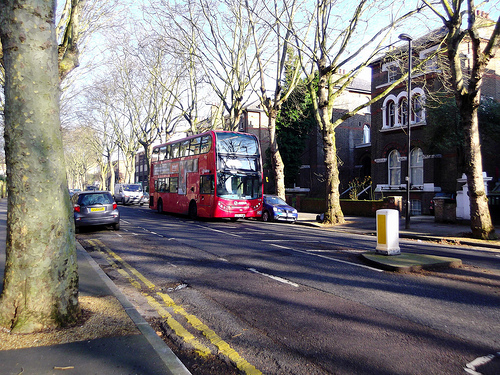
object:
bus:
[148, 131, 263, 222]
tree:
[0, 0, 88, 339]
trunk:
[3, 42, 85, 332]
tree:
[423, 0, 500, 239]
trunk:
[460, 138, 492, 239]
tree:
[279, 0, 414, 226]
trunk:
[321, 152, 346, 224]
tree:
[236, 0, 314, 201]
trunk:
[267, 145, 287, 199]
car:
[74, 191, 121, 233]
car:
[261, 194, 297, 224]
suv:
[114, 184, 144, 206]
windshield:
[217, 173, 262, 199]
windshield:
[216, 132, 258, 155]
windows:
[383, 91, 423, 128]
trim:
[382, 54, 428, 132]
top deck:
[151, 130, 262, 155]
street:
[74, 229, 500, 368]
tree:
[90, 58, 123, 196]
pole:
[375, 209, 401, 256]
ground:
[362, 249, 463, 270]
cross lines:
[82, 248, 263, 375]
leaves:
[287, 111, 299, 134]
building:
[370, 9, 498, 214]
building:
[294, 64, 370, 195]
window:
[388, 150, 402, 185]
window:
[408, 147, 424, 185]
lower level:
[151, 177, 215, 195]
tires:
[157, 199, 164, 213]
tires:
[188, 202, 197, 219]